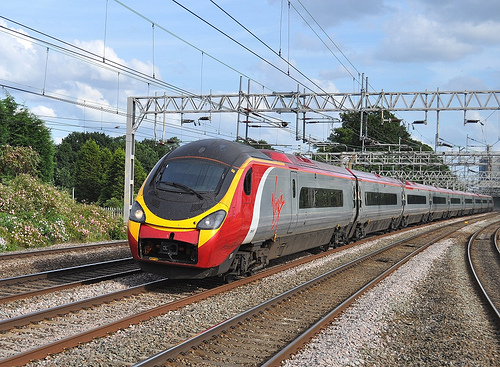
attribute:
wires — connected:
[1, 1, 439, 171]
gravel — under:
[4, 208, 495, 365]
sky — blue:
[3, 1, 498, 197]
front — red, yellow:
[128, 140, 278, 273]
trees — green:
[3, 96, 188, 221]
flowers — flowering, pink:
[0, 145, 131, 242]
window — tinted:
[294, 184, 345, 206]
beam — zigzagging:
[126, 92, 496, 120]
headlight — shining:
[131, 202, 149, 224]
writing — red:
[270, 174, 285, 227]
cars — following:
[348, 164, 496, 238]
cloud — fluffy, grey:
[2, 20, 182, 135]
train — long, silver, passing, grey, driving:
[129, 140, 492, 287]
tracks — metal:
[0, 278, 210, 363]